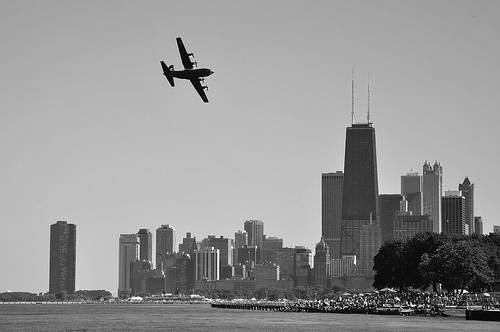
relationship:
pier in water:
[205, 301, 290, 311] [3, 305, 499, 331]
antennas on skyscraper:
[345, 77, 373, 126] [342, 121, 381, 288]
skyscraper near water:
[342, 121, 381, 288] [3, 305, 499, 331]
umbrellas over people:
[342, 286, 407, 299] [318, 284, 482, 313]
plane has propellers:
[159, 35, 222, 107] [185, 50, 218, 92]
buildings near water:
[38, 164, 500, 291] [3, 305, 499, 331]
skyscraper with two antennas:
[342, 121, 381, 288] [345, 77, 373, 126]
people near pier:
[318, 284, 482, 313] [205, 301, 290, 311]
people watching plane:
[318, 284, 482, 313] [159, 35, 222, 107]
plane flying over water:
[159, 35, 222, 107] [3, 305, 499, 331]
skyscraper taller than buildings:
[342, 121, 381, 288] [38, 164, 500, 291]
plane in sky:
[159, 35, 222, 107] [1, 1, 499, 290]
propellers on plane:
[185, 50, 218, 92] [159, 35, 222, 107]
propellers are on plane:
[185, 50, 218, 92] [159, 35, 222, 107]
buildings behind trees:
[38, 164, 500, 291] [375, 229, 499, 298]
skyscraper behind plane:
[342, 121, 381, 288] [159, 35, 222, 107]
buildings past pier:
[38, 164, 500, 291] [205, 301, 290, 311]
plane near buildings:
[159, 35, 222, 107] [38, 164, 500, 291]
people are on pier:
[318, 284, 482, 313] [205, 301, 290, 311]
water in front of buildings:
[3, 305, 499, 331] [38, 164, 500, 291]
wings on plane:
[173, 32, 212, 107] [159, 35, 222, 107]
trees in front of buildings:
[375, 229, 499, 298] [38, 164, 500, 291]